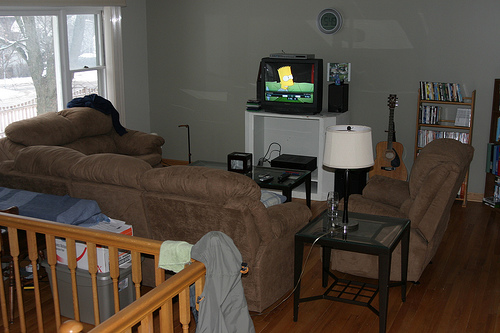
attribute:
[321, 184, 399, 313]
table — glass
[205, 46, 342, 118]
tv — black, small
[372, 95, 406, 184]
guitar — wood, acoustic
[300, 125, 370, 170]
lampshade — white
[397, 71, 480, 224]
shelf — wood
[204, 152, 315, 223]
side table — black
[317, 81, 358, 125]
speaker — large, black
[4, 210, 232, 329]
crib — large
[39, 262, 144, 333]
container — grey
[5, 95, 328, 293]
couch — large, edged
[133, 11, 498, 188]
wall — white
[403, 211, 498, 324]
floor — brown, wooden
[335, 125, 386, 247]
lamp — black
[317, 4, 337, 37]
clock — silver, digital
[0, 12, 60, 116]
tree — bare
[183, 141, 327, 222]
table — black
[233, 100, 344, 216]
stand — white